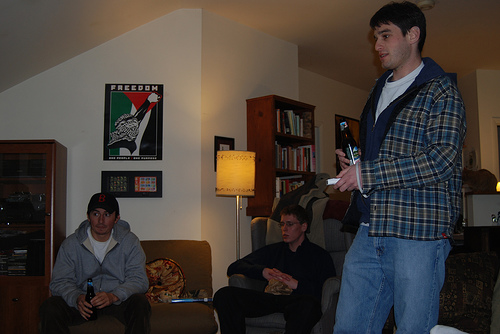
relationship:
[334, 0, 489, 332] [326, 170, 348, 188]
man have control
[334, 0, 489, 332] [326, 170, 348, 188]
man holding control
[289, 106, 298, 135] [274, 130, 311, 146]
book on shelf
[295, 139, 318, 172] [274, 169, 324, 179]
book on shelf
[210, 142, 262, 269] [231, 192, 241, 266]
lamp has pole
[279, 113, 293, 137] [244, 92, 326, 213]
book on shelf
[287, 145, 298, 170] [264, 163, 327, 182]
book on shelf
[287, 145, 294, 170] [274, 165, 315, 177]
book on shelf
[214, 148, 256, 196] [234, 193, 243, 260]
lamp shade on pole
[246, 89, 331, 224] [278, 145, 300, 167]
book case with book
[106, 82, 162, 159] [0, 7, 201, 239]
art decor affixed to wall